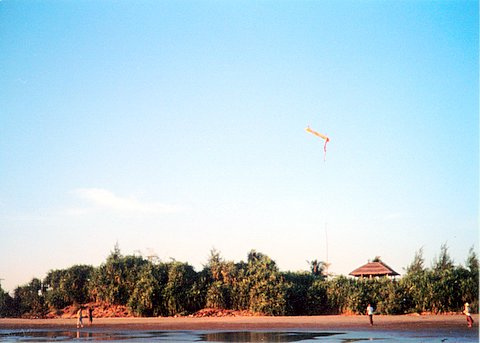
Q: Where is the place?
A: A beach.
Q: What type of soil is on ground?
A: Sand.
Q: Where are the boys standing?
A: Sand.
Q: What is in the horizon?
A: Trees.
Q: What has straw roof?
A: Hut.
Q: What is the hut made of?
A: Straw.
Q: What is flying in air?
A: Kite.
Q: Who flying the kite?
A: A boy.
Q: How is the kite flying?
A: Wind.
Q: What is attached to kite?
A: String.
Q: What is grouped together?
A: The trees.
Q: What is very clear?
A: The day.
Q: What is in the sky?
A: Clouds.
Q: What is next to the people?
A: Water.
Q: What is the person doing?
A: Flying a kite.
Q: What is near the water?
A: Trees.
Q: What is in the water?
A: Reflection.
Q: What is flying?
A: A kite.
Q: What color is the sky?
A: Blue.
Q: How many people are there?
A: 4.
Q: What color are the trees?
A: Green.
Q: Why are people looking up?
A: To look at the kite.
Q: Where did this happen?
A: In the outdoors.